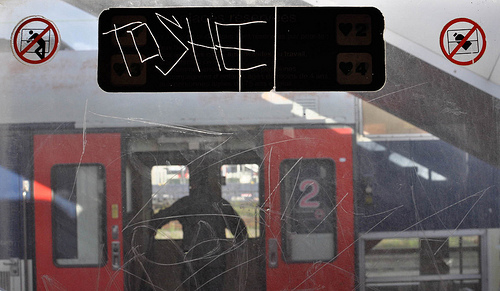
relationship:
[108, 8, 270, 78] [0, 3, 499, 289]
graffiti on window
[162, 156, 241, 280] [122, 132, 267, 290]
person walking out door way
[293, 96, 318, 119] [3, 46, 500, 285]
ac vent on tram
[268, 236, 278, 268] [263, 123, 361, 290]
handle on door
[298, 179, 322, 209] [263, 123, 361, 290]
number 2 on door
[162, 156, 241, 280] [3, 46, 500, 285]
person inside tram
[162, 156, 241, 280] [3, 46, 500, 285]
person on tram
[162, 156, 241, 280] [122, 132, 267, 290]
person standing in door way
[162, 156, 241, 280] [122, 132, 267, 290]
person inside door way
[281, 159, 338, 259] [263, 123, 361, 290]
window on door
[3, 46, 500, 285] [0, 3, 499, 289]
tram behind window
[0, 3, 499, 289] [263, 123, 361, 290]
window on door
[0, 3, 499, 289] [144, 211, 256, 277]
window covered with scratches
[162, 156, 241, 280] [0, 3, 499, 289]
person standing in front of window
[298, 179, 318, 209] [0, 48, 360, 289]
number 2 on train car